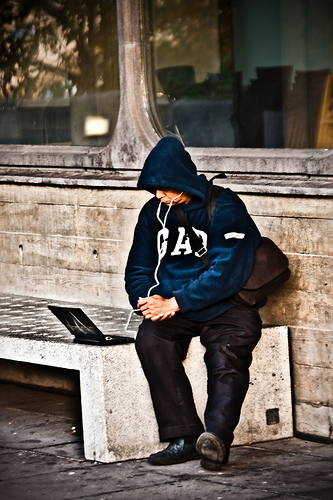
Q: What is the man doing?
A: Using a computer.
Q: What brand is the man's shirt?
A: Gap.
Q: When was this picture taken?
A: Daytime.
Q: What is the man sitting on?
A: A bench.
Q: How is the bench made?
A: Of stone.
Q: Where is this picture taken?
A: The street.